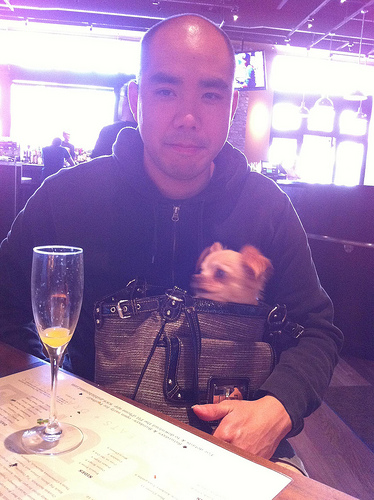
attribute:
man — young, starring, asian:
[0, 17, 344, 457]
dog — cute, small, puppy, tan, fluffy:
[192, 241, 270, 307]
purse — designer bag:
[91, 290, 282, 431]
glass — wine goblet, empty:
[31, 244, 84, 448]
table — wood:
[2, 453, 264, 500]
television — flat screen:
[234, 49, 267, 93]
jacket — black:
[0, 132, 310, 243]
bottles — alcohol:
[20, 145, 41, 164]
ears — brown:
[242, 244, 274, 282]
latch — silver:
[96, 290, 140, 324]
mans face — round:
[141, 28, 232, 175]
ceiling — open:
[236, 2, 373, 49]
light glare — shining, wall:
[272, 48, 374, 185]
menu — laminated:
[0, 413, 162, 499]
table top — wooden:
[274, 465, 354, 499]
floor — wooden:
[305, 403, 372, 481]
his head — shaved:
[135, 13, 236, 177]